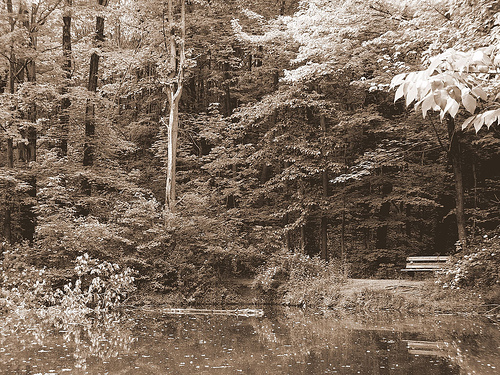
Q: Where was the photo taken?
A: Near a lake.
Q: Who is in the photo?
A: No one.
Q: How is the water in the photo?
A: Calm.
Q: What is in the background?
A: A forest.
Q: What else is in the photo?
A: A park bench.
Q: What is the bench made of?
A: Wood.